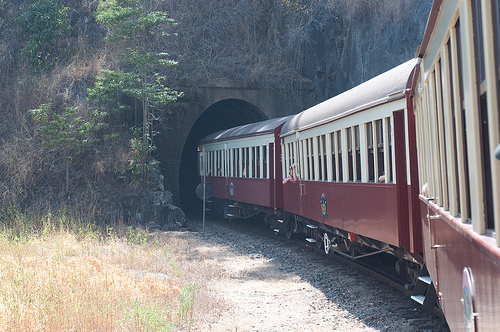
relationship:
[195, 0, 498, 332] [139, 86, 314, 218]
car going into tunnel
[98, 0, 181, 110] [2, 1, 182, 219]
foliage of tree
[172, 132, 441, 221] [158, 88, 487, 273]
windows on train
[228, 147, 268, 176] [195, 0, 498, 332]
windows on car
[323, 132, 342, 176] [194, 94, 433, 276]
window on train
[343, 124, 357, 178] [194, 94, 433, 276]
window on train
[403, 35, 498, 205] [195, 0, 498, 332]
windows on car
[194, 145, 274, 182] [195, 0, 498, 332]
windows on car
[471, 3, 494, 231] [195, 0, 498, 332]
window on car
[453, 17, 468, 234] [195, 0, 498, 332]
window on car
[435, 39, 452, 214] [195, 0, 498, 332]
window on car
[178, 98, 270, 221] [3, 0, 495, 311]
train tunnel in mountain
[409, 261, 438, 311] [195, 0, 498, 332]
steps on car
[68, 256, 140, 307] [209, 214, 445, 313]
dead grass by track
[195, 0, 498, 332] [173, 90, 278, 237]
car entering tunnel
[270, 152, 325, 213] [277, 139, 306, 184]
people leaning out of window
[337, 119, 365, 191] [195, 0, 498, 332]
windows on car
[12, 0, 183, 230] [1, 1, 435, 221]
trees alongside mountain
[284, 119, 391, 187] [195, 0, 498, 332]
windows on car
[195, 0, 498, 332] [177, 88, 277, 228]
car exiting tunnel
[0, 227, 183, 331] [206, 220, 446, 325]
dead grass by track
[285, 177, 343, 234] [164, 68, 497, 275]
sign of train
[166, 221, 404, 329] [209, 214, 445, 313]
gravel by track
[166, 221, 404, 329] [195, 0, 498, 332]
gravel by car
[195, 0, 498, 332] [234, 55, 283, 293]
car leaving tunnel